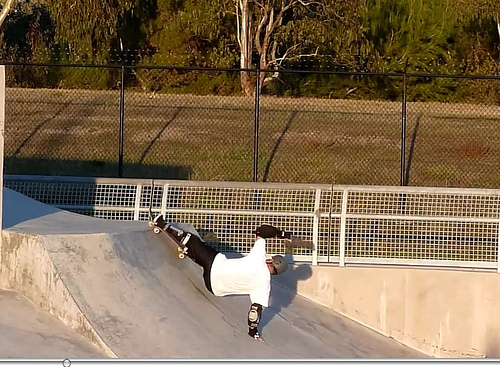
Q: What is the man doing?
A: Skateboarding.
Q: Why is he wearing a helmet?
A: Protection.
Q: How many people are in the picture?
A: One.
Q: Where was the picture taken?
A: Skate park.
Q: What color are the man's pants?
A: Black.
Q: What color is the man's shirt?
A: White.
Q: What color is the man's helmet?
A: Gold.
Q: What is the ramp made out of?
A: Concrete.